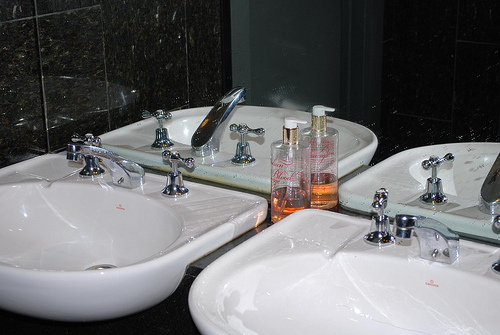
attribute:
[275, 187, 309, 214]
soap — nearly empty, almost empty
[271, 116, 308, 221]
bottle — reflected, clear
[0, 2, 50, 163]
wall tile — black, gold, dark brown, reflected, marble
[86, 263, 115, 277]
sink drain — silver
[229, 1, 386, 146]
door — reflected, closed, white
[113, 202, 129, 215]
letters — red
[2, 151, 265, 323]
sink — white, porcelain, reflected, circular, large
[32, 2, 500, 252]
mirror — reflecting, large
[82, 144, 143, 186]
faucet — silver, off, chrome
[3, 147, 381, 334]
counter — black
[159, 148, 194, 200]
handle — silver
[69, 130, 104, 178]
handle — silver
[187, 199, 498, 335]
sink — white